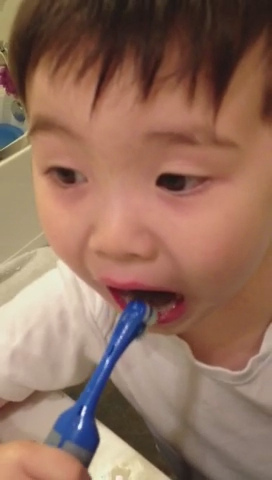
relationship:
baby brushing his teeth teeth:
[0, 0, 272, 478] [157, 299, 175, 317]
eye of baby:
[37, 159, 90, 189] [0, 0, 272, 478]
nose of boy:
[87, 200, 157, 263] [8, 0, 271, 336]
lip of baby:
[100, 277, 175, 290] [0, 0, 272, 478]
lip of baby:
[108, 297, 189, 322] [0, 0, 272, 478]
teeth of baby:
[98, 272, 204, 333] [0, 0, 272, 478]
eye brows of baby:
[145, 119, 246, 151] [0, 0, 272, 478]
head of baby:
[18, 1, 271, 323] [0, 0, 272, 478]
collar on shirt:
[177, 340, 265, 381] [0, 254, 270, 477]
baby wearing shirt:
[0, 0, 272, 478] [0, 254, 270, 477]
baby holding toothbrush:
[0, 0, 272, 478] [42, 295, 157, 465]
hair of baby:
[3, 0, 271, 144] [0, 0, 272, 478]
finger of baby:
[27, 438, 97, 478] [2, 1, 268, 478]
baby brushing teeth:
[0, 0, 272, 478] [153, 294, 181, 319]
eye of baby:
[135, 146, 210, 200] [0, 0, 272, 478]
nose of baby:
[87, 200, 157, 261] [0, 0, 272, 478]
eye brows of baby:
[145, 119, 246, 165] [0, 0, 272, 478]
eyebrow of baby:
[27, 115, 77, 142] [0, 0, 272, 478]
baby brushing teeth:
[0, 0, 272, 478] [101, 281, 187, 324]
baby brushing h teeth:
[2, 1, 268, 478] [116, 289, 181, 319]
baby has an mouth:
[0, 0, 272, 478] [102, 274, 187, 324]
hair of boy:
[3, 0, 271, 135] [31, 57, 232, 350]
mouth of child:
[100, 274, 186, 324] [97, 268, 184, 319]